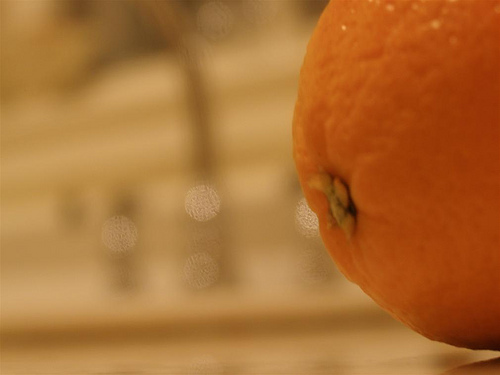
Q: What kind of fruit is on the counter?
A: Orange.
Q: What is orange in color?
A: An orange.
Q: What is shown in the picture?
A: A fresh orange.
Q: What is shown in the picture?
A: A fresh orange.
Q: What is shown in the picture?
A: An orange.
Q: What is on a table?
A: An orange.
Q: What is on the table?
A: An orange.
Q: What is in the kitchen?
A: An orange.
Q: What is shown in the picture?
A: An orange.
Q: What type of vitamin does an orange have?
A: Vitamin C.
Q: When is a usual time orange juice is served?
A: Morning.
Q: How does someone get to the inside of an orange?
A: Peel it.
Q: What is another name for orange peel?
A: Rind.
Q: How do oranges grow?
A: On trees.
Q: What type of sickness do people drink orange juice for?
A: Colds.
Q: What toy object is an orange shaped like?
A: A ball.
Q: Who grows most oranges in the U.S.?
A: Farmers.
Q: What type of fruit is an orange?
A: Citrus.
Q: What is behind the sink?
A: White wooden window sill.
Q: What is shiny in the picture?
A: Metal handles of faucet.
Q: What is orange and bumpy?
A: The surface of the orange.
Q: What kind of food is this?
A: Fruit.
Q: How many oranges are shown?
A: One.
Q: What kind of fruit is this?
A: An orange.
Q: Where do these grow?
A: On trees.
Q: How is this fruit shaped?
A: Sphere.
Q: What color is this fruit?
A: Orange.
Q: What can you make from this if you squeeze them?
A: Orange Juice.